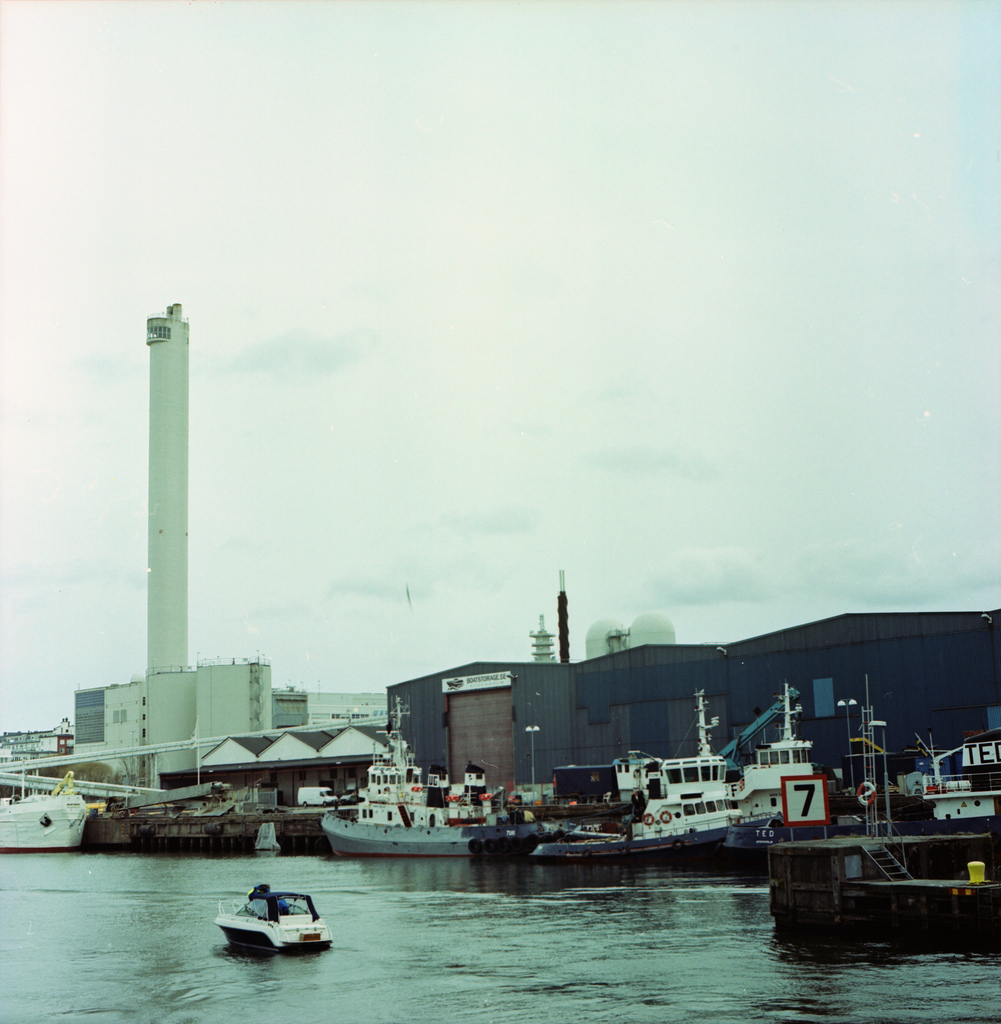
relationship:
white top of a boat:
[353, 735, 449, 827] [288, 684, 584, 869]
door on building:
[479, 764, 611, 827] [355, 571, 957, 865]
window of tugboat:
[202, 871, 331, 972] [200, 851, 352, 980]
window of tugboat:
[220, 889, 329, 956] [210, 860, 339, 961]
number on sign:
[788, 788, 820, 820] [781, 758, 859, 859]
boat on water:
[211, 857, 340, 955] [448, 924, 660, 1007]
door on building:
[564, 751, 620, 820] [382, 653, 806, 896]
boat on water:
[310, 768, 528, 891] [479, 940, 737, 989]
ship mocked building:
[301, 758, 821, 963] [357, 618, 941, 745]